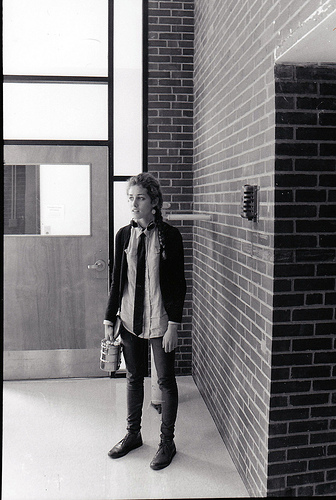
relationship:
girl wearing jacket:
[96, 170, 197, 492] [163, 234, 182, 298]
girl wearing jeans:
[96, 170, 197, 492] [122, 342, 168, 441]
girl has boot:
[96, 170, 197, 492] [152, 433, 186, 474]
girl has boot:
[96, 170, 197, 492] [107, 431, 145, 462]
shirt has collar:
[124, 236, 167, 332] [133, 227, 142, 236]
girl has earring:
[96, 170, 197, 492] [151, 208, 156, 216]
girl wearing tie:
[96, 170, 197, 492] [135, 242, 145, 335]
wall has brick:
[149, 3, 333, 497] [274, 204, 321, 222]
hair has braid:
[145, 175, 166, 213] [156, 216, 168, 257]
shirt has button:
[124, 236, 167, 332] [145, 316, 149, 320]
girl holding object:
[96, 170, 197, 492] [95, 339, 122, 379]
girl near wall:
[96, 170, 197, 492] [149, 3, 333, 497]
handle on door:
[87, 262, 108, 275] [6, 148, 108, 377]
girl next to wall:
[96, 170, 197, 492] [149, 3, 333, 497]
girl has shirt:
[96, 170, 197, 492] [124, 236, 167, 332]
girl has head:
[96, 170, 197, 492] [126, 178, 171, 227]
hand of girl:
[164, 329, 179, 352] [96, 170, 197, 492]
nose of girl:
[132, 203, 137, 208] [96, 170, 197, 492]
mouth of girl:
[130, 207, 142, 213] [96, 170, 197, 492]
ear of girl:
[150, 200, 162, 207] [96, 170, 197, 492]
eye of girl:
[127, 196, 137, 201] [96, 170, 197, 492]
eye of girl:
[140, 197, 147, 200] [96, 170, 197, 492]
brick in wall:
[272, 407, 312, 423] [149, 3, 333, 497]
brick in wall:
[217, 149, 241, 159] [149, 3, 333, 497]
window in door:
[6, 164, 94, 237] [6, 148, 108, 377]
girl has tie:
[96, 170, 197, 492] [135, 242, 145, 335]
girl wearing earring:
[96, 170, 197, 492] [151, 208, 156, 216]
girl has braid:
[96, 170, 197, 492] [156, 216, 168, 257]